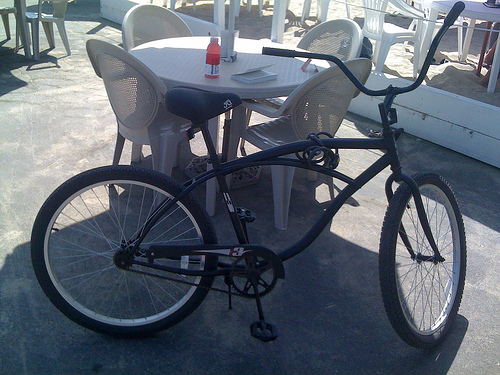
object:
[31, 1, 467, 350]
bike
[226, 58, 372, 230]
chair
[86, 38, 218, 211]
chair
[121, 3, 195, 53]
chair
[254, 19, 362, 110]
chair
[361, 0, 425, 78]
chair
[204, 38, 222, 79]
bottle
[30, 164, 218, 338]
wheel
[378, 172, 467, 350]
wheel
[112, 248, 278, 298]
chain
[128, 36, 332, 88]
table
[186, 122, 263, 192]
stand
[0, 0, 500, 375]
ground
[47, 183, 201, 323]
wiring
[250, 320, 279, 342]
pedal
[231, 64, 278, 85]
book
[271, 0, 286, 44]
pole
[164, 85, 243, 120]
seat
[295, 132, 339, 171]
lock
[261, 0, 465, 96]
handle bars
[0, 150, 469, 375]
shadow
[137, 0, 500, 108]
sand